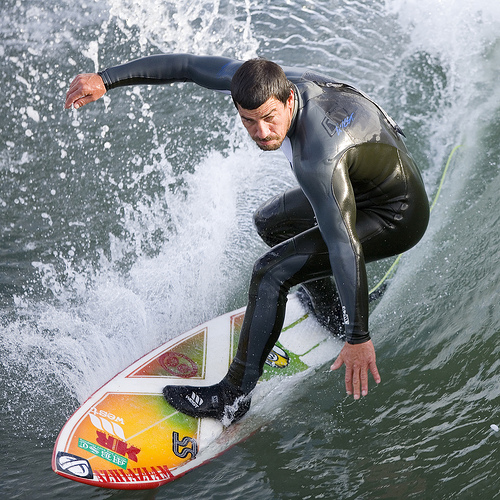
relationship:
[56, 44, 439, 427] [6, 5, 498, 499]
man surfing in ocean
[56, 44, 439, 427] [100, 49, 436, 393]
man wearing wet suit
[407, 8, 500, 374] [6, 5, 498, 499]
waves in ocean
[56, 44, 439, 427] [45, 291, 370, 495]
man in on top surfboard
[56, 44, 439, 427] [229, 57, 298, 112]
man has dark hair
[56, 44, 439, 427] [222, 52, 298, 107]
man has dark hair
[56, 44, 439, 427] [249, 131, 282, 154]
man has goatee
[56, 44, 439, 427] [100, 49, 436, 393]
man wearing wetsuit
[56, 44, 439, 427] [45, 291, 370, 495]
man on surfboard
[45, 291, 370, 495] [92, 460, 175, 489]
surfboard has wording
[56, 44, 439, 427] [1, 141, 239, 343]
man riding a wave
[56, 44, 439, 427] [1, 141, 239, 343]
man surfing wave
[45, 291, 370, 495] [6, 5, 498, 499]
surfboard on a wave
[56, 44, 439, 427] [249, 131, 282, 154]
man with a goatee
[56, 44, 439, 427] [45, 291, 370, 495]
surfer on a surfboard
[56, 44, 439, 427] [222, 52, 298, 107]
man with brown hair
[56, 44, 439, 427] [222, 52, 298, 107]
man has brown hair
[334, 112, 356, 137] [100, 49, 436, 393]
writing on wet suit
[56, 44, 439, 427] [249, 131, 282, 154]
man has mustache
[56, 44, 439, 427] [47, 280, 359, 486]
man keeping his balance on surfboard